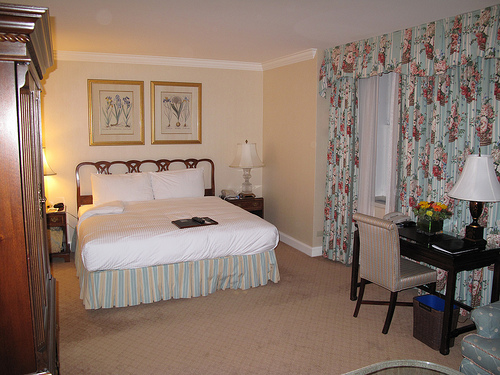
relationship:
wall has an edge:
[264, 48, 314, 254] [313, 48, 316, 256]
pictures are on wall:
[87, 78, 203, 145] [38, 58, 265, 252]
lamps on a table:
[41, 139, 266, 200] [222, 195, 265, 218]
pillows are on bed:
[92, 167, 204, 203] [75, 158, 282, 310]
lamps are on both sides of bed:
[41, 141, 267, 200] [75, 158, 282, 310]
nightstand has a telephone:
[222, 195, 265, 218] [223, 188, 239, 199]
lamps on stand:
[41, 139, 266, 200] [222, 195, 265, 218]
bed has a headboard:
[75, 158, 282, 310] [76, 157, 216, 207]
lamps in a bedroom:
[41, 139, 266, 200] [4, 5, 494, 374]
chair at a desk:
[351, 213, 438, 335] [350, 217, 499, 345]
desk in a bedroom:
[350, 217, 499, 345] [4, 5, 494, 374]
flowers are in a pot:
[414, 200, 450, 220] [416, 216, 444, 234]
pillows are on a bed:
[92, 167, 204, 203] [75, 158, 282, 310]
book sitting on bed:
[171, 216, 219, 229] [75, 158, 282, 310]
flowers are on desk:
[414, 200, 450, 220] [350, 217, 499, 345]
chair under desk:
[351, 213, 438, 335] [350, 217, 499, 345]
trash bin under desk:
[412, 292, 457, 350] [350, 217, 499, 345]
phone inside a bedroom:
[375, 209, 407, 225] [4, 5, 494, 374]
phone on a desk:
[375, 209, 407, 225] [348, 209, 498, 352]